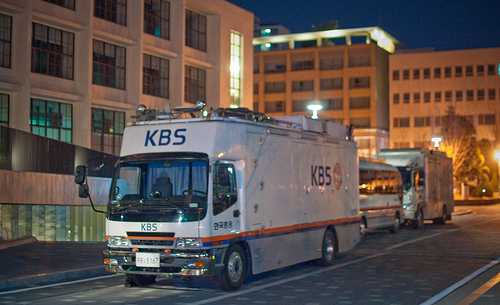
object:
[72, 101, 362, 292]
vehicule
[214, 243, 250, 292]
front tire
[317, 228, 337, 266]
left rear tire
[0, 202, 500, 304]
street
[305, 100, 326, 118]
street light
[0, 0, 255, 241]
building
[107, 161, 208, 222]
windshield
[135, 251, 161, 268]
license plate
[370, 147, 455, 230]
truck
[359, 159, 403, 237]
bus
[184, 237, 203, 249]
headlight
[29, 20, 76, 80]
window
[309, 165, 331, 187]
logo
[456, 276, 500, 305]
line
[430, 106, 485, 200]
tree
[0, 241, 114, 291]
sidewalk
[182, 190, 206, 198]
wheel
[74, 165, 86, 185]
side mirror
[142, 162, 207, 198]
curtain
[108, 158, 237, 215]
driving compartment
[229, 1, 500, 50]
sky